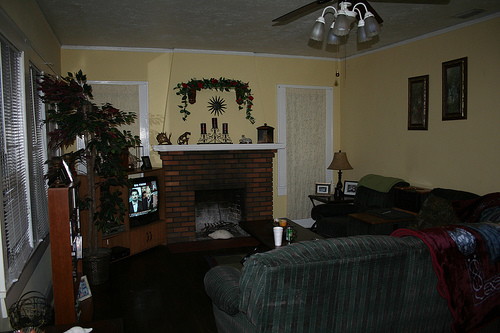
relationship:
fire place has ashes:
[153, 143, 287, 244] [209, 229, 234, 240]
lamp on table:
[328, 149, 354, 199] [309, 194, 355, 205]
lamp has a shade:
[328, 149, 354, 199] [326, 149, 351, 171]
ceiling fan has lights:
[272, 0, 385, 47] [309, 15, 382, 46]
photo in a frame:
[318, 185, 327, 193] [315, 183, 330, 196]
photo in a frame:
[347, 183, 357, 193] [343, 179, 358, 195]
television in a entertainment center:
[128, 175, 161, 228] [79, 168, 166, 264]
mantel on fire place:
[156, 143, 284, 152] [153, 143, 287, 244]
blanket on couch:
[390, 220, 499, 332] [203, 186, 499, 332]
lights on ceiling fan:
[309, 15, 382, 46] [272, 0, 385, 47]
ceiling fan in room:
[272, 0, 385, 47] [1, 0, 499, 332]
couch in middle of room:
[203, 186, 499, 332] [1, 0, 499, 332]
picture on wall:
[440, 55, 467, 121] [339, 13, 499, 196]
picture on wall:
[408, 75, 428, 130] [339, 13, 499, 196]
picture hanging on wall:
[440, 55, 467, 121] [339, 13, 499, 196]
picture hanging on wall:
[408, 75, 428, 130] [339, 13, 499, 196]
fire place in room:
[153, 143, 287, 244] [1, 0, 499, 332]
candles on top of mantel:
[197, 117, 234, 144] [156, 143, 284, 152]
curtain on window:
[286, 87, 327, 220] [275, 82, 335, 196]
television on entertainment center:
[128, 175, 161, 228] [79, 168, 166, 264]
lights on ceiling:
[309, 15, 382, 46] [36, 1, 499, 58]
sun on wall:
[207, 96, 225, 116] [169, 50, 265, 143]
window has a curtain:
[275, 82, 335, 196] [286, 87, 327, 220]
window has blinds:
[0, 9, 60, 293] [1, 37, 55, 284]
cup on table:
[273, 225, 284, 246] [238, 218, 325, 251]